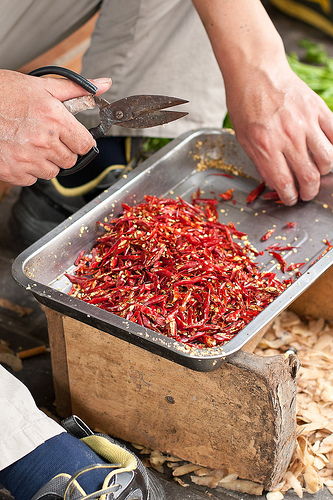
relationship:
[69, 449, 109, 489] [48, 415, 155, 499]
foot in shoe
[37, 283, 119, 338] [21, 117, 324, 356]
edge of tray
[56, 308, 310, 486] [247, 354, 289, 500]
block of wood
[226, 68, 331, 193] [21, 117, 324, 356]
hand in tray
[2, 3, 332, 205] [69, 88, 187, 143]
man holding shears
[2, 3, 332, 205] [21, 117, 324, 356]
man over tray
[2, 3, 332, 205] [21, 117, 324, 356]
man working over tray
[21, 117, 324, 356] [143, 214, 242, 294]
tray of peppers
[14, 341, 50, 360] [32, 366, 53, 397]
cigarette on ground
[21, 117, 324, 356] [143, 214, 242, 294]
pan of peppers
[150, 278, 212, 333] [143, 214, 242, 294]
pile of peppers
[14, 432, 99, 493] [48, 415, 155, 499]
sock in shoe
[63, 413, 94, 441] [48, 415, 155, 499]
tab on shoes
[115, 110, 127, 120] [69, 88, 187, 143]
screw in scissors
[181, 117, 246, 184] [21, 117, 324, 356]
corner of pan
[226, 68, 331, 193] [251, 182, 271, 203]
hand picking up pepper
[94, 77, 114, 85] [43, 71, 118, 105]
nail on thumb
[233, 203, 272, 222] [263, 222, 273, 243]
seeds of chili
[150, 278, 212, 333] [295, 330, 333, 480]
pile of shavings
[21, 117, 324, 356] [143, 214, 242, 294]
tray full o peppers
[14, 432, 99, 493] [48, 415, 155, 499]
sock inside shoe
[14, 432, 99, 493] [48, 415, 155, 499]
sock inside of shoe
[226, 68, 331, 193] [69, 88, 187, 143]
hand grasping shears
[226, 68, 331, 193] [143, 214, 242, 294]
hand scooping peppers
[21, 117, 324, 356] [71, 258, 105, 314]
tray with chilis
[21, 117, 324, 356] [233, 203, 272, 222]
tray with seeds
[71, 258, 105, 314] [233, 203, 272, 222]
chilis and seeds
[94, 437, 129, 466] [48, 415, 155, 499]
interior of shoes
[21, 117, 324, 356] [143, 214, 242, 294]
tin full of peppers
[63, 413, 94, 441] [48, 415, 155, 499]
tag on shoe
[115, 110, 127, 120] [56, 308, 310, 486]
screw in block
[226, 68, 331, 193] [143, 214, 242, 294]
hand holding peppers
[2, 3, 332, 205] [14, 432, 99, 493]
man wearing sock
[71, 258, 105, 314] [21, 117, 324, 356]
chilis on tray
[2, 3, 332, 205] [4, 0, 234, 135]
man wearing pants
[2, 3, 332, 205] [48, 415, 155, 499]
man has shoe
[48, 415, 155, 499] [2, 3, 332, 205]
shoe of man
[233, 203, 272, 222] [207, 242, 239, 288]
seeds from chilies